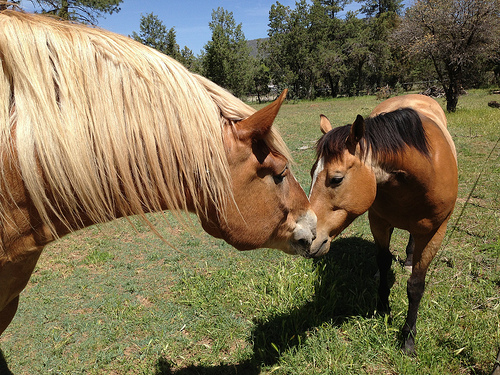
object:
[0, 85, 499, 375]
grass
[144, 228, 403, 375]
shadow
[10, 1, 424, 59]
sky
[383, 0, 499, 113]
trees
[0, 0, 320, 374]
horse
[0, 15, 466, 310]
two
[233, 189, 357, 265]
touching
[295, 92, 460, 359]
horse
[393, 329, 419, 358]
hooves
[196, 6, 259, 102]
tree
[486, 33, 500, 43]
leaves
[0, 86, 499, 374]
field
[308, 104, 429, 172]
hair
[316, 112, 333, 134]
ear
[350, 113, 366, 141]
ear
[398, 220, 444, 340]
leg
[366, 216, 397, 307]
leg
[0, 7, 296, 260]
hair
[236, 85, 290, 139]
ear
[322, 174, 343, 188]
eye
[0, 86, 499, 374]
ground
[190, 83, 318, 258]
head